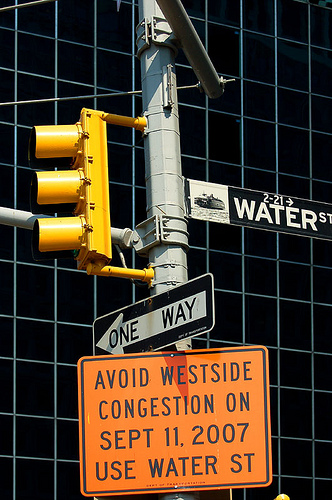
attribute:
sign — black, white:
[44, 260, 262, 403]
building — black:
[2, 2, 328, 497]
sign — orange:
[76, 344, 272, 495]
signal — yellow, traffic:
[26, 111, 103, 273]